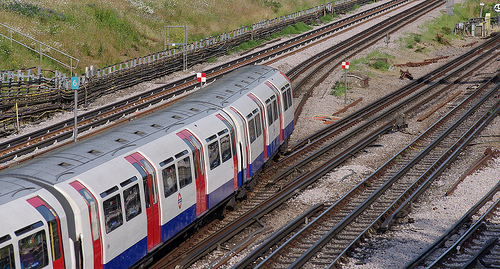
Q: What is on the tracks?
A: A train.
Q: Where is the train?
A: On the tracks.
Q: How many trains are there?
A: One.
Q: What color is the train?
A: Red, white, and blue.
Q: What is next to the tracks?
A: A hill.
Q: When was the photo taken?
A: During the day.